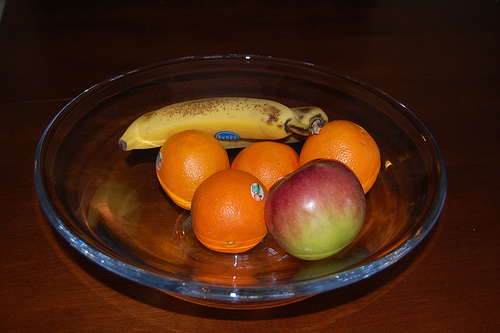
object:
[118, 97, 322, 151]
banana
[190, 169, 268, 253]
oranges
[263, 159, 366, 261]
apple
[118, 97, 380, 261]
fruit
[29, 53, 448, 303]
plate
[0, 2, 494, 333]
surface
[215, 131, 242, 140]
sticker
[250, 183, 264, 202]
sticker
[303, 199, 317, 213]
glare